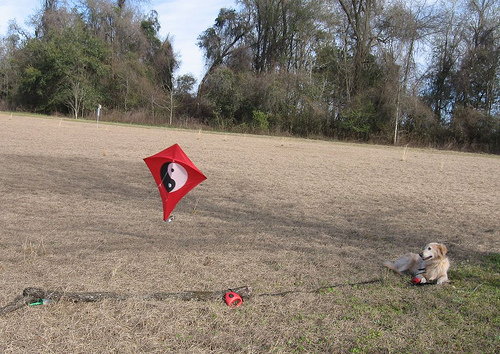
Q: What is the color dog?
A: Cream.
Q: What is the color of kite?
A: Red.